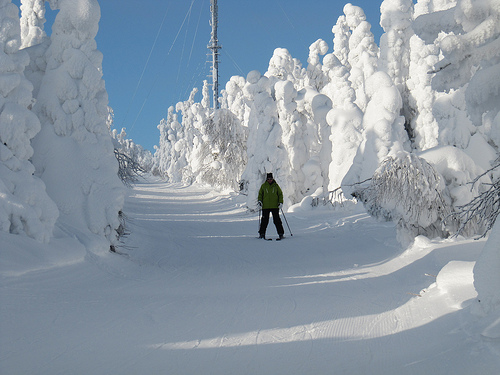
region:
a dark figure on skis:
[254, 172, 288, 241]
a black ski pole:
[279, 203, 296, 240]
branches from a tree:
[347, 151, 499, 233]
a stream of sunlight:
[153, 258, 474, 352]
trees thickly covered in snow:
[0, 0, 497, 265]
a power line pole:
[205, 1, 222, 117]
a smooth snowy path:
[1, 160, 453, 373]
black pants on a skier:
[257, 208, 282, 237]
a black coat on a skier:
[253, 181, 285, 204]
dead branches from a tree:
[116, 146, 145, 183]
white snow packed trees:
[1, 1, 498, 245]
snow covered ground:
[4, 168, 499, 373]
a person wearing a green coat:
[256, 170, 295, 242]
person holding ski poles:
[254, 171, 294, 240]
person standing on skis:
[256, 172, 297, 242]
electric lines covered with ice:
[111, 0, 260, 137]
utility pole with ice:
[207, 1, 222, 107]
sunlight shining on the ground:
[151, 235, 478, 352]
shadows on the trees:
[235, 75, 330, 206]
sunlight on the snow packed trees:
[306, 8, 431, 202]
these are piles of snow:
[234, 1, 499, 208]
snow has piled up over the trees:
[7, 0, 164, 267]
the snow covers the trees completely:
[252, 23, 488, 194]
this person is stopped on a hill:
[234, 156, 333, 272]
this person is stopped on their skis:
[223, 148, 318, 261]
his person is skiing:
[247, 148, 317, 275]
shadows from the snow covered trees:
[166, 214, 493, 374]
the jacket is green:
[237, 148, 314, 247]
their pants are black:
[252, 206, 307, 243]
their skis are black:
[245, 220, 305, 249]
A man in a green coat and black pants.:
[256, 172, 283, 241]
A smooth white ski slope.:
[27, 168, 426, 374]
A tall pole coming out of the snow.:
[206, 1, 221, 108]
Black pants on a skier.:
[256, 208, 286, 243]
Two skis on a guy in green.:
[253, 232, 287, 242]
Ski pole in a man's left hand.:
[278, 204, 293, 238]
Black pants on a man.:
[258, 208, 287, 240]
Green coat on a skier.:
[256, 179, 284, 211]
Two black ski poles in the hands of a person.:
[255, 203, 295, 240]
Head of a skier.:
[264, 172, 275, 184]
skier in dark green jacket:
[249, 172, 295, 241]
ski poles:
[281, 201, 298, 238]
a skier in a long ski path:
[113, 115, 466, 373]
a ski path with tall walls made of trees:
[6, 9, 496, 369]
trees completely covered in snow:
[304, 53, 412, 204]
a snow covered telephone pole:
[202, 0, 222, 117]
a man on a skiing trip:
[244, 162, 296, 252]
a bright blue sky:
[98, 0, 200, 94]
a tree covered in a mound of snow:
[30, 0, 138, 247]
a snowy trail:
[79, 80, 226, 225]